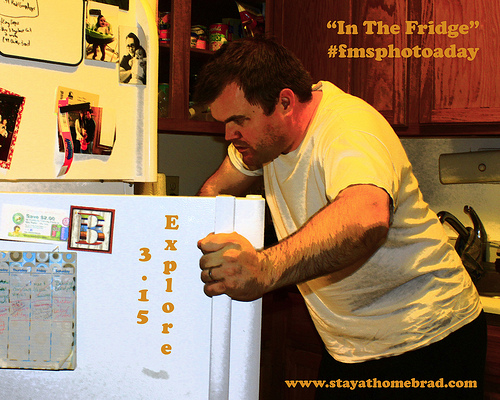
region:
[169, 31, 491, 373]
A man looking into a refridgerator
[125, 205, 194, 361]
Letters and numbers on a refrigerator door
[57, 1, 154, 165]
Photos on a freezer door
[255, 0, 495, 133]
Kitchen cabinets made of wood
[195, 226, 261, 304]
A wedding ring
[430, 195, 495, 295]
Knives on a counter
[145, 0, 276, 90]
Food in a kitchen cabinet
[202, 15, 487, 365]
A man in a white t-shirt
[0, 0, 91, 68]
Dry erase board on a freezer door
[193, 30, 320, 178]
A man with short brown hair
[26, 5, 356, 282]
a man looking into a refrigertator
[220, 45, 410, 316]
a man wearing a white shirt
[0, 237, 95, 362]
a calendar on a refrigerator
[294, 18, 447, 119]
wooden kitchen cabinets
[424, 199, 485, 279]
a kitchen sink faucet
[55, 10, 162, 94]
photographs on a refrigerator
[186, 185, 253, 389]
a refrigerator door handle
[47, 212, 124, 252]
refrigerator magnet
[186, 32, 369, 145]
a man with brown hair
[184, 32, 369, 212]
a man leaning down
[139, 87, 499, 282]
the guy in white t-shirt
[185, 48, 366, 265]
the guy in white t-shirt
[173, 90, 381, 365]
the guy in white t-shirt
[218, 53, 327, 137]
Man has dark hair.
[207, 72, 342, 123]
Man has short hair.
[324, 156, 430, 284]
Man is wearing white shirt.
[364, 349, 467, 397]
Man is wearing dark pants.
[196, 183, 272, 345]
Man holding on to fridge handle.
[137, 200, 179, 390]
Yellow lettering on fridge.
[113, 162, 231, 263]
Fridge door is open.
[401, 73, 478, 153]
Cupboards in fridge are brown.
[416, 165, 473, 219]
Wall is white in kitchen.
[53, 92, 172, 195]
Pictures are on fridge.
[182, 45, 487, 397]
man staring into the fridge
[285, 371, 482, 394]
website address written in yellow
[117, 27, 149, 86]
photo hanging on the fridge of a woman and a small child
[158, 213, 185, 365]
letter magnets on the fridge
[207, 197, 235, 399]
long white fridge handle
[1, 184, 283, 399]
fridge door is open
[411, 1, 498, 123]
wooden cabinet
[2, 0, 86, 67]
whiteboard with writing on it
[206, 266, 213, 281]
ring on the ring finger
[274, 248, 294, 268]
patch of dark arm hair